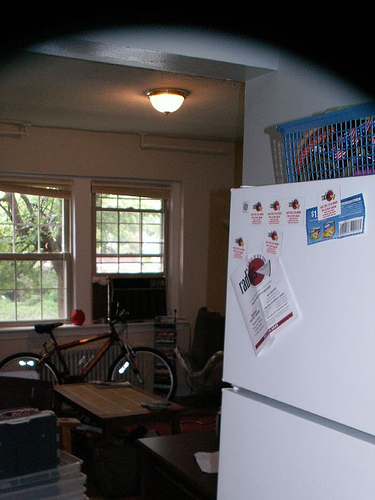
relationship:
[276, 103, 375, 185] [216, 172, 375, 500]
laundry on a freezer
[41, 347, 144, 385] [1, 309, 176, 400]
radiator behind a bike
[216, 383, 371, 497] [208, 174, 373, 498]
door on refrigerator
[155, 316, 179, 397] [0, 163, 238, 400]
cd stand against wall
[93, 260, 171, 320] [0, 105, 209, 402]
conditioner on wall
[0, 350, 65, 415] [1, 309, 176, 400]
wheel on bike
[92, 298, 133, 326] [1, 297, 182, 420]
handles on bike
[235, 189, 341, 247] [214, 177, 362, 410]
magnets on fridge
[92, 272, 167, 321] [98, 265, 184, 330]
conditioner in window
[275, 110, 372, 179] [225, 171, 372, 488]
laundry on top of fridge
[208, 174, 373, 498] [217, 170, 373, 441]
refrigerator with freezer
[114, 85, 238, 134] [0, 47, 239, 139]
light in ceiling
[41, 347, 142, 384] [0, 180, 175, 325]
radiator under windows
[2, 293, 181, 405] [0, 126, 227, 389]
bicycle against wall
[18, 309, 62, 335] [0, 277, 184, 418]
seat of bicycle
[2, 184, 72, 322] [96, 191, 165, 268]
window to outside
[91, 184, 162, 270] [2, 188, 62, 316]
window to outside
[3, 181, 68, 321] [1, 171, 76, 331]
trees behind window